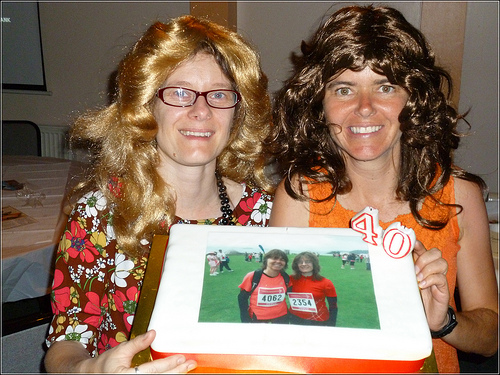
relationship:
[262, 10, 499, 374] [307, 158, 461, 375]
girl wearing dress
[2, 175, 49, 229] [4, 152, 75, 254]
items on table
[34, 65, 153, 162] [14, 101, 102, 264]
chair behind table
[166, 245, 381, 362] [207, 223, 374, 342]
grass in field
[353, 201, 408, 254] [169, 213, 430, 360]
40 on cake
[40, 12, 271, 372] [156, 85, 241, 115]
woman wearing glasses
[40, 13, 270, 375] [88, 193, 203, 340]
woman wearing dress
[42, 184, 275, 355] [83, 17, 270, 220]
dress on woman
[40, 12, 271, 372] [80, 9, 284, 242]
woman wearing wig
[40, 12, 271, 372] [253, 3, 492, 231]
woman wearing hair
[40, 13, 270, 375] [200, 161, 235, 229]
woman wearing necklace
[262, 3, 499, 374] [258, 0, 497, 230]
girl with hair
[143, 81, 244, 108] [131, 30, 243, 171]
glasses on face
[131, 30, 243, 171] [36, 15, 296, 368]
face of woman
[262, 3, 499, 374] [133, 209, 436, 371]
girl holding cake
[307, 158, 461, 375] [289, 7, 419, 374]
dress on woman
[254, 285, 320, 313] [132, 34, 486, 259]
numbers on women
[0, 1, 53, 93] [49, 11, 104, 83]
board on wall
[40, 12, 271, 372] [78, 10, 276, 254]
woman with blonde hair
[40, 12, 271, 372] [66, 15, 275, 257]
woman wears blonde hair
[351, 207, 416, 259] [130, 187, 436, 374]
40 on cake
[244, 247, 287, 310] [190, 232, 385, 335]
woman in picture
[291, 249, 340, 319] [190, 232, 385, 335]
woman in picture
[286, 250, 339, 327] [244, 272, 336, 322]
woman wears red tops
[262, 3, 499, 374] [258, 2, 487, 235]
girl wearing wig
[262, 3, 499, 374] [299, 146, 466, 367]
girl wearing dress